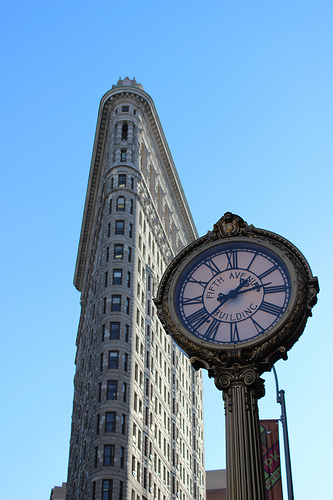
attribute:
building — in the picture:
[43, 68, 330, 499]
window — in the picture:
[104, 264, 132, 283]